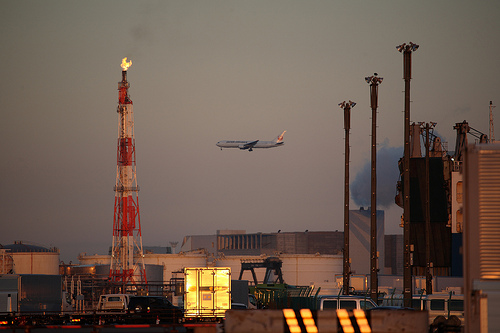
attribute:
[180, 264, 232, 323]
truck — large, white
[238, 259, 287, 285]
structure — green, metal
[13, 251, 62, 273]
silo — concrete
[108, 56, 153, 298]
tower — tall, white, red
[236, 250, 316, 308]
machine — industrial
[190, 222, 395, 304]
building — large, white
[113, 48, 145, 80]
flame — red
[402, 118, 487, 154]
machinery — heavy, mechanical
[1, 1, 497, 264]
sky — foggy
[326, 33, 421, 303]
poles — tall, brown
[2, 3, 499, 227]
sky — darkened, gray